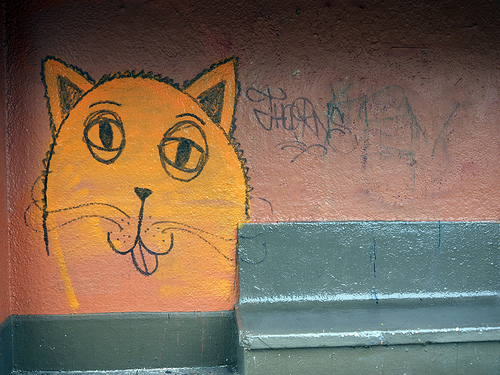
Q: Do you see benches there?
A: Yes, there is a bench.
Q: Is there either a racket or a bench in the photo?
A: Yes, there is a bench.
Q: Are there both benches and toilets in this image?
A: No, there is a bench but no toilets.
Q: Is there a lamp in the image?
A: No, there are no lamps.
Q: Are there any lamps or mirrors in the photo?
A: No, there are no lamps or mirrors.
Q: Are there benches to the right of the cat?
A: Yes, there is a bench to the right of the cat.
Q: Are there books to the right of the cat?
A: No, there is a bench to the right of the cat.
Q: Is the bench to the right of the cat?
A: Yes, the bench is to the right of the cat.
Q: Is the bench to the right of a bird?
A: No, the bench is to the right of the cat.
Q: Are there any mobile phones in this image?
A: No, there are no mobile phones.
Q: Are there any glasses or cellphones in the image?
A: No, there are no cellphones or glasses.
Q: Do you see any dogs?
A: No, there are no dogs.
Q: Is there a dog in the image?
A: No, there are no dogs.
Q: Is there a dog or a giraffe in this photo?
A: No, there are no dogs or giraffes.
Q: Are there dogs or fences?
A: No, there are no fences or dogs.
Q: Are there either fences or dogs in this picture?
A: No, there are no fences or dogs.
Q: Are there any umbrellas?
A: No, there are no umbrellas.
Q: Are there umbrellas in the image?
A: No, there are no umbrellas.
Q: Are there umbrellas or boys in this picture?
A: No, there are no umbrellas or boys.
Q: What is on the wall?
A: The graffiti is on the wall.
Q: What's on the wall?
A: The graffiti is on the wall.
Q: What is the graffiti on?
A: The graffiti is on the wall.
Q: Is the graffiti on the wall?
A: Yes, the graffiti is on the wall.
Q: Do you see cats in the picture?
A: Yes, there is a cat.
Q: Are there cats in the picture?
A: Yes, there is a cat.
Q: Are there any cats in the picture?
A: Yes, there is a cat.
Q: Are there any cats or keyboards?
A: Yes, there is a cat.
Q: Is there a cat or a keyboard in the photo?
A: Yes, there is a cat.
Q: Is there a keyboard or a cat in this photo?
A: Yes, there is a cat.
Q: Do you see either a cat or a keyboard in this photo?
A: Yes, there is a cat.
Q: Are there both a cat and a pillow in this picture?
A: No, there is a cat but no pillows.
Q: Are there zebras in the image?
A: No, there are no zebras.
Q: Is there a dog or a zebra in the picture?
A: No, there are no zebras or dogs.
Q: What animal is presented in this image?
A: The animal is a cat.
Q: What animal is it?
A: The animal is a cat.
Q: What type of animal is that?
A: That is a cat.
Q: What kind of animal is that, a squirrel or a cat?
A: That is a cat.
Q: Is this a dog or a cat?
A: This is a cat.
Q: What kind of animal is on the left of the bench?
A: The animal is a cat.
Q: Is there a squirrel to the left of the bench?
A: No, there is a cat to the left of the bench.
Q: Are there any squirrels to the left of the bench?
A: No, there is a cat to the left of the bench.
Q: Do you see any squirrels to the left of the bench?
A: No, there is a cat to the left of the bench.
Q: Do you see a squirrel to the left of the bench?
A: No, there is a cat to the left of the bench.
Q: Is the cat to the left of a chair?
A: No, the cat is to the left of the bench.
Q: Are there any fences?
A: No, there are no fences.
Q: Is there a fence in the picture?
A: No, there are no fences.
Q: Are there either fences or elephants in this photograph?
A: No, there are no fences or elephants.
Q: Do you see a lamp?
A: No, there are no lamps.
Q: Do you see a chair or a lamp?
A: No, there are no lamps or chairs.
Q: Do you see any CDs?
A: No, there are no cds.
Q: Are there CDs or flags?
A: No, there are no CDs or flags.